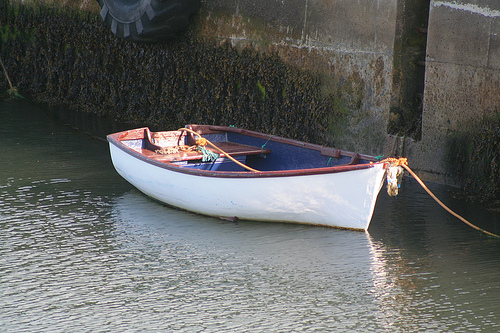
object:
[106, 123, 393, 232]
boat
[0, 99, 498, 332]
water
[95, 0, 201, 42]
tire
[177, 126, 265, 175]
rope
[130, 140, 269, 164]
seat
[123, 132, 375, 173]
inside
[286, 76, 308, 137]
seaweed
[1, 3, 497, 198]
wall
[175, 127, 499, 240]
rope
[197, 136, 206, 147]
knot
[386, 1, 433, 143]
drain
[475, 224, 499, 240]
moss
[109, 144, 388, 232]
side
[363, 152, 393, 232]
tip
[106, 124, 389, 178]
edge